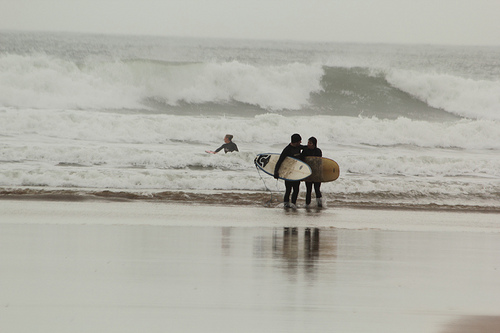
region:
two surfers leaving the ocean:
[250, 128, 339, 209]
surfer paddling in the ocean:
[207, 131, 247, 159]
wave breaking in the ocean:
[14, 45, 499, 114]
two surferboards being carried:
[253, 145, 342, 185]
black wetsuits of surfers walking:
[279, 143, 323, 200]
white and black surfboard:
[255, 150, 310, 182]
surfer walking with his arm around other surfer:
[272, 125, 332, 204]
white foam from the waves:
[4, 54, 499, 195]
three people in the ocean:
[206, 125, 338, 215]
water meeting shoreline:
[2, 178, 497, 213]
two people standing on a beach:
[251, 122, 354, 225]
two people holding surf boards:
[246, 137, 346, 217]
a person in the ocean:
[200, 120, 250, 175]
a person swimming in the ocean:
[209, 122, 246, 179]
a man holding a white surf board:
[251, 128, 307, 199]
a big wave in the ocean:
[71, 60, 460, 125]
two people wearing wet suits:
[263, 134, 335, 212]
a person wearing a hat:
[274, 126, 306, 170]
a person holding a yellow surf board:
[298, 137, 343, 192]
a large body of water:
[1, 22, 466, 101]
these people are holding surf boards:
[236, 142, 365, 203]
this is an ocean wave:
[167, 40, 462, 125]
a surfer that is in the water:
[203, 114, 243, 188]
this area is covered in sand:
[51, 228, 423, 309]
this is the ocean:
[21, 12, 458, 132]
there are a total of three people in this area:
[181, 97, 364, 242]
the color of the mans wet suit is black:
[270, 129, 306, 213]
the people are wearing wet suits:
[274, 133, 341, 218]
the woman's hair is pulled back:
[211, 128, 246, 150]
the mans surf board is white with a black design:
[254, 151, 315, 189]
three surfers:
[176, 94, 365, 231]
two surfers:
[253, 127, 348, 214]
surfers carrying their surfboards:
[247, 120, 351, 219]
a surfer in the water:
[200, 124, 250, 166]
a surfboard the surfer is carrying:
[252, 150, 312, 182]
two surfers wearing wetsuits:
[246, 123, 348, 224]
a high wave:
[96, 46, 211, 131]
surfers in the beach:
[179, 98, 354, 231]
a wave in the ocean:
[351, 52, 457, 138]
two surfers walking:
[252, 130, 355, 230]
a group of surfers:
[177, 88, 406, 258]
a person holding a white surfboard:
[255, 130, 307, 214]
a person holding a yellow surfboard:
[301, 132, 346, 207]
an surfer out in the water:
[196, 117, 248, 182]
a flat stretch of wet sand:
[27, 205, 485, 325]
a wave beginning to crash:
[36, 40, 489, 137]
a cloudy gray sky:
[13, 5, 495, 41]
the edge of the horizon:
[12, 23, 498, 68]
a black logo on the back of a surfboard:
[246, 147, 271, 177]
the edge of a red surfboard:
[201, 136, 222, 167]